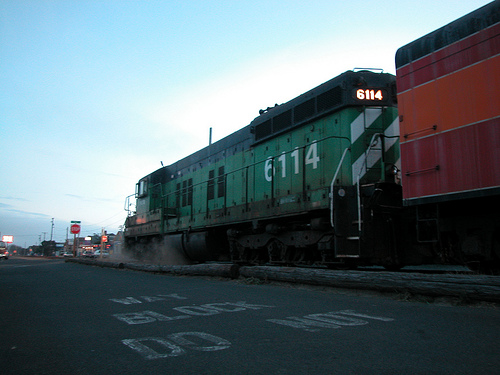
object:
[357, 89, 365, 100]
number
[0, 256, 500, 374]
road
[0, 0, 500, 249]
sky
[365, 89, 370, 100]
numbers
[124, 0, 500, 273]
train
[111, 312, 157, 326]
paint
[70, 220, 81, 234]
sign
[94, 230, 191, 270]
smoke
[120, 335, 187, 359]
letters